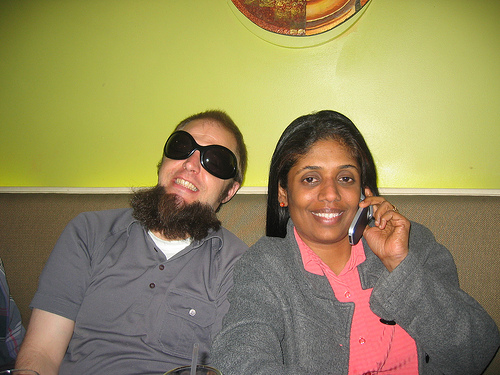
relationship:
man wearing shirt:
[13, 104, 254, 375] [28, 196, 249, 375]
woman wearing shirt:
[205, 106, 499, 375] [294, 221, 420, 373]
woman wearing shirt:
[205, 106, 499, 375] [210, 212, 498, 373]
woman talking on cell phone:
[205, 106, 499, 375] [346, 186, 375, 246]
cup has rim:
[153, 360, 220, 374] [160, 362, 229, 374]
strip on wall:
[0, 186, 499, 198] [3, 3, 499, 340]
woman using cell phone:
[205, 106, 499, 375] [346, 186, 375, 246]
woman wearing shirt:
[205, 106, 499, 375] [28, 196, 249, 375]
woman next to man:
[205, 106, 499, 375] [13, 104, 254, 375]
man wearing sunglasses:
[13, 104, 254, 375] [158, 129, 241, 186]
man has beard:
[13, 104, 254, 375] [127, 184, 223, 238]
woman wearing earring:
[205, 106, 499, 375] [279, 199, 287, 207]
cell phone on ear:
[346, 186, 375, 246] [355, 187, 363, 203]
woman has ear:
[205, 106, 499, 375] [355, 187, 363, 203]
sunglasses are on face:
[158, 129, 241, 186] [157, 121, 242, 208]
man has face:
[13, 104, 254, 375] [157, 121, 242, 208]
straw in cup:
[189, 340, 206, 371] [153, 360, 220, 374]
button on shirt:
[343, 290, 353, 301] [294, 221, 420, 373]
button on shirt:
[355, 337, 365, 347] [294, 221, 420, 373]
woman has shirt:
[205, 106, 499, 375] [294, 221, 420, 373]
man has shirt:
[13, 104, 254, 375] [28, 196, 249, 375]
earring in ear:
[279, 199, 287, 207] [272, 178, 289, 207]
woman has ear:
[205, 106, 499, 375] [272, 178, 289, 207]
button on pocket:
[184, 305, 199, 322] [149, 292, 215, 356]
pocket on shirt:
[149, 292, 215, 356] [28, 196, 249, 375]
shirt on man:
[28, 196, 249, 375] [13, 104, 254, 375]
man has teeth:
[13, 104, 254, 375] [175, 178, 196, 193]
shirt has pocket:
[28, 196, 249, 375] [149, 292, 215, 356]